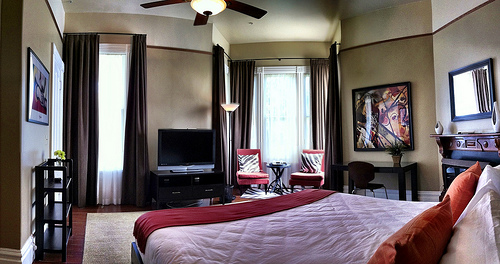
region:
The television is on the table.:
[147, 120, 242, 210]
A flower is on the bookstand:
[41, 153, 90, 250]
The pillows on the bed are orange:
[386, 164, 454, 261]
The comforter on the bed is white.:
[153, 191, 431, 255]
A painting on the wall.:
[350, 78, 431, 156]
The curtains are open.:
[64, 36, 149, 208]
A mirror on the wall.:
[443, 71, 497, 123]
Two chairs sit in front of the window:
[236, 142, 335, 196]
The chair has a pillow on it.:
[233, 144, 275, 191]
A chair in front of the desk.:
[346, 156, 408, 196]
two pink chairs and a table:
[228, 137, 336, 197]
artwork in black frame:
[345, 85, 424, 159]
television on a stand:
[140, 115, 235, 205]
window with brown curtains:
[227, 55, 334, 188]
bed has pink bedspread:
[115, 191, 494, 262]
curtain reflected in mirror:
[437, 57, 497, 120]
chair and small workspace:
[340, 152, 424, 195]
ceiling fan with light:
[140, 2, 271, 39]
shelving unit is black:
[34, 155, 78, 257]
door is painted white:
[49, 45, 71, 245]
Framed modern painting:
[352, 81, 414, 149]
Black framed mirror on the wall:
[446, 56, 493, 118]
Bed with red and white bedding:
[138, 160, 498, 262]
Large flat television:
[152, 125, 229, 199]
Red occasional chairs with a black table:
[234, 141, 330, 192]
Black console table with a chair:
[337, 157, 427, 207]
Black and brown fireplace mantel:
[431, 128, 498, 193]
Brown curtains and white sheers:
[65, 30, 151, 207]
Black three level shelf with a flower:
[31, 147, 81, 262]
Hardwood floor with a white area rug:
[67, 206, 129, 263]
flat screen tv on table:
[141, 113, 233, 185]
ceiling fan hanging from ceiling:
[127, 3, 299, 28]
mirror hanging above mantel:
[441, 63, 493, 140]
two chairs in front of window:
[235, 128, 325, 197]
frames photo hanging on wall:
[23, 42, 61, 148]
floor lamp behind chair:
[216, 77, 240, 199]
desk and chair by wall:
[333, 147, 439, 201]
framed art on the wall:
[346, 79, 418, 159]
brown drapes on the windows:
[63, 27, 346, 186]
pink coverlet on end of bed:
[115, 188, 404, 248]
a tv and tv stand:
[150, 123, 235, 205]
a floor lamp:
[216, 99, 245, 194]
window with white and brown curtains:
[61, 27, 157, 209]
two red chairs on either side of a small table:
[236, 141, 330, 193]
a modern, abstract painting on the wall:
[348, 83, 420, 155]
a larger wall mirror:
[443, 59, 497, 126]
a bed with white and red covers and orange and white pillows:
[141, 158, 497, 263]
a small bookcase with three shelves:
[31, 151, 81, 259]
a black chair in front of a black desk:
[332, 140, 421, 200]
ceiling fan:
[123, 1, 294, 28]